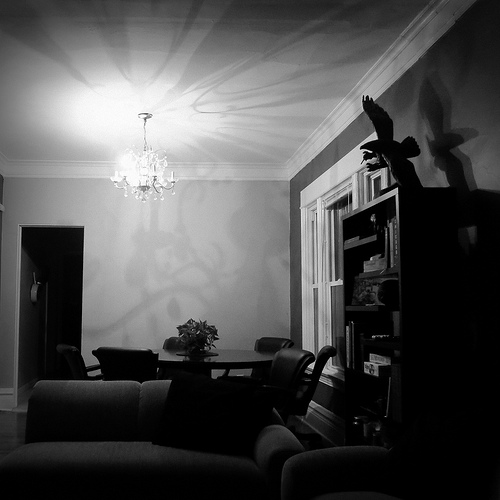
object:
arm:
[255, 421, 304, 474]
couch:
[0, 371, 304, 498]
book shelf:
[330, 187, 398, 430]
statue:
[355, 93, 421, 188]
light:
[108, 123, 172, 202]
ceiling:
[62, 30, 281, 75]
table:
[148, 344, 276, 373]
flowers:
[169, 318, 218, 353]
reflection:
[68, 2, 241, 84]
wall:
[239, 193, 278, 220]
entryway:
[16, 224, 85, 402]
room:
[0, 0, 499, 497]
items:
[362, 252, 387, 272]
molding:
[221, 162, 269, 181]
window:
[300, 164, 388, 387]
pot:
[189, 345, 207, 357]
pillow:
[150, 370, 277, 452]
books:
[382, 218, 398, 268]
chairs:
[254, 344, 316, 421]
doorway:
[0, 363, 46, 416]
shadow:
[117, 238, 205, 303]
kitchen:
[27, 326, 80, 376]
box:
[344, 319, 361, 367]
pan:
[28, 270, 43, 305]